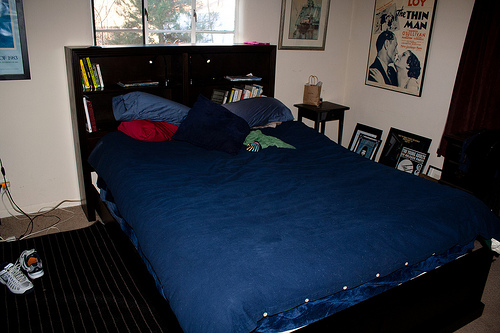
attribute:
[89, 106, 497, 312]
spread — blue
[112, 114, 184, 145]
pillow — red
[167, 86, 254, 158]
pillow — blue, navy blue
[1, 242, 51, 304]
sneaker — white, athletic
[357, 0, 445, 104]
poster — black, white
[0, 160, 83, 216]
electrical cord — black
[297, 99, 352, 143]
table — small, wood, square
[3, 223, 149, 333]
floor — black, striped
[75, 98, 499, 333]
comforte — blue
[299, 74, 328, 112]
bag — paper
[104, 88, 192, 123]
pillow — long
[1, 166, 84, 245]
cords — electrical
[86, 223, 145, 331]
line — thin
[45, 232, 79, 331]
line — thin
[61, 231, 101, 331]
line — thin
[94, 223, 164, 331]
line — thin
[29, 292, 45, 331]
line — thin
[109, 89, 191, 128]
pillow case — blue